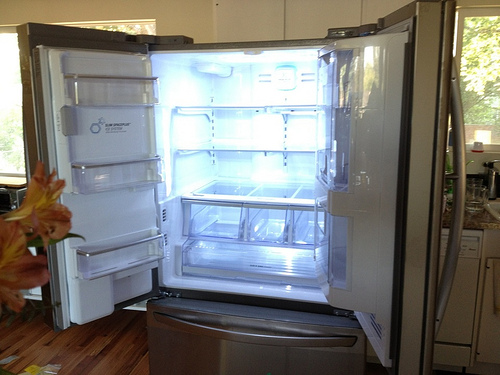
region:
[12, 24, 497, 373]
Refrigerator has both of its doors opened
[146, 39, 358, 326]
Refrigerator has no food inside of it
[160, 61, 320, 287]
Plastic shelves and see through drawers fill the inside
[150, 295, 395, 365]
The freezer portion of the refrigerator is still closed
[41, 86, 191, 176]
The ice maker unit is in the left door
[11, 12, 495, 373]
The brand new refrigerator is completely empty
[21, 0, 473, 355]
ope upper refrigerator doors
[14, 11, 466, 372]
empty stainless steel fridge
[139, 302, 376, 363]
lower closed freezer portion of fridge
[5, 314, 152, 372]
wooden floors in kitchen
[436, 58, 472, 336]
stainless steel door handle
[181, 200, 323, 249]
plastic boxes in fridge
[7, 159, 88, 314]
orange flowers in foreground of picture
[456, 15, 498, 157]
kitchen window with trees visible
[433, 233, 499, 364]
white lichen stove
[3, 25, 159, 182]
large window in white kitchen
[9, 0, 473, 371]
empty, open refrigerator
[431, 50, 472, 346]
refrigerator door handle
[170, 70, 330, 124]
shelf in refrigerator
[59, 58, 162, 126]
door shelf in refrigerator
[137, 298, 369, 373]
bottom freezer portion of refrigerator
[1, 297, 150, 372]
hardwood floors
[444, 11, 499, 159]
window above counter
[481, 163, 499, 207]
silver cannister on countertop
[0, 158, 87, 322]
yellow and orange flower petals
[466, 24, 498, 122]
trees outside of window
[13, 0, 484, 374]
open upper doors of fridge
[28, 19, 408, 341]
empty upper portion of fridge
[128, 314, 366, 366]
lower freezer portion of stainless steel fridge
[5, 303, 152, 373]
wooden floor of kitchen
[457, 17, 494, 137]
window with nature seen outside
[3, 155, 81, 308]
orange tiger Lilly flower blossoms in foreground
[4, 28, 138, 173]
large window emitting sunshine in kitchen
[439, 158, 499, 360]
white kitchen cabinets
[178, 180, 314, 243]
clear plastic drawers inside frdge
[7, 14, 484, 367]
stainless steel fridge with open doors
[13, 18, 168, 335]
Large dark metal door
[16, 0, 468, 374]
Large open metal refrigerator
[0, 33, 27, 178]
Large wide glass window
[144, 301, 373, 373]
Large wide metal door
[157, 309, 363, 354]
Long thick metal handle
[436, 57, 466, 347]
Long vertical metal handle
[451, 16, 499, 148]
Large tall glass window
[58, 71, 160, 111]
Large long plastic tray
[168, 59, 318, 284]
the fridge is empty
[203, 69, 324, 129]
the lights are flourescent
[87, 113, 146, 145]
words on the door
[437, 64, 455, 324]
the handle is silver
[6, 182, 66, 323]
the leaves are brown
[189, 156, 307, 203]
the shelves are plastic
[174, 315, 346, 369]
the handle is on freezer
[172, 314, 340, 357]
the handle is silver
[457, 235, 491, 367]
the cabinet is white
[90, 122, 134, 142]
words on the fridge door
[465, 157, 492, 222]
appliance on the counter